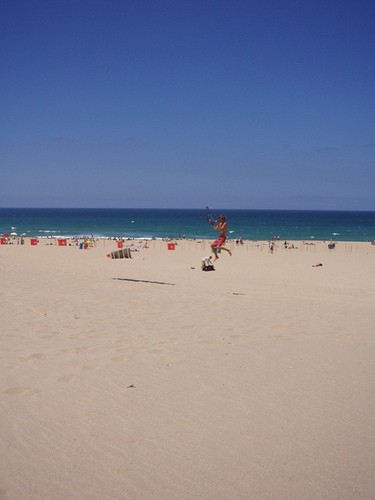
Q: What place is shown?
A: It is a beach.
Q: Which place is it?
A: It is a beach.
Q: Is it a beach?
A: Yes, it is a beach.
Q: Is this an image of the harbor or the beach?
A: It is showing the beach.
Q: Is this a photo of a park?
A: No, the picture is showing a beach.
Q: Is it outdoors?
A: Yes, it is outdoors.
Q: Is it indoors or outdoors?
A: It is outdoors.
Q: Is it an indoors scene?
A: No, it is outdoors.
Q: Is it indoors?
A: No, it is outdoors.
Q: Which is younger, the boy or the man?
A: The boy is younger than the man.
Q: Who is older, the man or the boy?
A: The man is older than the boy.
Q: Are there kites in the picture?
A: No, there are no kites.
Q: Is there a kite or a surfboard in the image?
A: No, there are no kites or surfboards.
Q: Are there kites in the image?
A: No, there are no kites.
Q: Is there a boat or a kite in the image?
A: No, there are no kites or boats.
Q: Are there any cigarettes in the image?
A: No, there are no cigarettes.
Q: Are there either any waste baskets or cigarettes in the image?
A: No, there are no cigarettes or waste baskets.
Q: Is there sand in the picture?
A: Yes, there is sand.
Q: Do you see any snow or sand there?
A: Yes, there is sand.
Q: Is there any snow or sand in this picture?
A: Yes, there is sand.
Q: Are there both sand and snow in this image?
A: No, there is sand but no snow.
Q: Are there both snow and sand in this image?
A: No, there is sand but no snow.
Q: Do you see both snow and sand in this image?
A: No, there is sand but no snow.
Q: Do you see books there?
A: No, there are no books.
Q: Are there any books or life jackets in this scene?
A: No, there are no books or life jackets.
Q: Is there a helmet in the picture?
A: No, there are no helmets.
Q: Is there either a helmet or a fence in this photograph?
A: No, there are no helmets or fences.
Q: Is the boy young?
A: Yes, the boy is young.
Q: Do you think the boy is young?
A: Yes, the boy is young.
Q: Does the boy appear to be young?
A: Yes, the boy is young.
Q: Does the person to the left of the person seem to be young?
A: Yes, the boy is young.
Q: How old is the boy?
A: The boy is young.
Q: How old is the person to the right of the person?
A: The boy is young.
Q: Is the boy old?
A: No, the boy is young.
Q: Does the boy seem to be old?
A: No, the boy is young.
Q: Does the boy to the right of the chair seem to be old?
A: No, the boy is young.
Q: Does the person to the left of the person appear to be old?
A: No, the boy is young.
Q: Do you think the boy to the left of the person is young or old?
A: The boy is young.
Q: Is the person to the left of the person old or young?
A: The boy is young.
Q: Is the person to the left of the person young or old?
A: The boy is young.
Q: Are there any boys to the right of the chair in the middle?
A: Yes, there is a boy to the right of the chair.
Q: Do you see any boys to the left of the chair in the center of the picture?
A: No, the boy is to the right of the chair.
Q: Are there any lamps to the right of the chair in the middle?
A: No, there is a boy to the right of the chair.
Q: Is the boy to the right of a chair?
A: Yes, the boy is to the right of a chair.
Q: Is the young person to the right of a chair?
A: Yes, the boy is to the right of a chair.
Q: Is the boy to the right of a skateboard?
A: No, the boy is to the right of a chair.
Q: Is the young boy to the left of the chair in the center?
A: No, the boy is to the right of the chair.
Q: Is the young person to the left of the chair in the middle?
A: No, the boy is to the right of the chair.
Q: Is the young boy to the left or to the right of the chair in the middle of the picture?
A: The boy is to the right of the chair.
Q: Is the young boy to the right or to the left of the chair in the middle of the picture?
A: The boy is to the right of the chair.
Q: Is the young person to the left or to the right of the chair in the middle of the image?
A: The boy is to the right of the chair.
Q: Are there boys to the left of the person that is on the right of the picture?
A: Yes, there is a boy to the left of the person.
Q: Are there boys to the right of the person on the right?
A: No, the boy is to the left of the person.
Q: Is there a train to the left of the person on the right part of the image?
A: No, there is a boy to the left of the person.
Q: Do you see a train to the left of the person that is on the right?
A: No, there is a boy to the left of the person.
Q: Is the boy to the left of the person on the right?
A: Yes, the boy is to the left of the person.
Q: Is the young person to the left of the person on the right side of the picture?
A: Yes, the boy is to the left of the person.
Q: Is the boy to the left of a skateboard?
A: No, the boy is to the left of the person.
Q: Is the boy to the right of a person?
A: No, the boy is to the left of a person.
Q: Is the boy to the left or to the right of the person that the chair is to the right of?
A: The boy is to the left of the person.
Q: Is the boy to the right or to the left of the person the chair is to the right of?
A: The boy is to the left of the person.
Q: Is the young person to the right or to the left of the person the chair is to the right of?
A: The boy is to the left of the person.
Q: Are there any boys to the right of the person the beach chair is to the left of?
A: Yes, there is a boy to the right of the person.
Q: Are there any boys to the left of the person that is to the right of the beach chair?
A: No, the boy is to the right of the person.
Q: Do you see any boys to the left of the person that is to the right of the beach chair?
A: No, the boy is to the right of the person.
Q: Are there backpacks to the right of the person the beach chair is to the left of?
A: No, there is a boy to the right of the person.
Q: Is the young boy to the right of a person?
A: Yes, the boy is to the right of a person.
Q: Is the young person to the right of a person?
A: Yes, the boy is to the right of a person.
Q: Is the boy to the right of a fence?
A: No, the boy is to the right of a person.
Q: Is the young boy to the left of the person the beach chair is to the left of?
A: No, the boy is to the right of the person.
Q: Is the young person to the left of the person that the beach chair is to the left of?
A: No, the boy is to the right of the person.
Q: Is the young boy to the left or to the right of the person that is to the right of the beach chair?
A: The boy is to the right of the person.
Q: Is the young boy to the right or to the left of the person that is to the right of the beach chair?
A: The boy is to the right of the person.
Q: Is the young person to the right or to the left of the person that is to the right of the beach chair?
A: The boy is to the right of the person.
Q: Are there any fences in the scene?
A: No, there are no fences.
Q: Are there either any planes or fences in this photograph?
A: No, there are no fences or planes.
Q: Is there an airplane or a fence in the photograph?
A: No, there are no fences or airplanes.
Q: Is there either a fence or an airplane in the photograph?
A: No, there are no fences or airplanes.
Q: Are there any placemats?
A: No, there are no placemats.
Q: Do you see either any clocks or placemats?
A: No, there are no placemats or clocks.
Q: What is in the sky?
A: The clouds are in the sky.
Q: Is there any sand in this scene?
A: Yes, there is sand.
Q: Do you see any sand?
A: Yes, there is sand.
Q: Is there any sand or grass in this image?
A: Yes, there is sand.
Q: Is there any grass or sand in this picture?
A: Yes, there is sand.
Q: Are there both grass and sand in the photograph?
A: No, there is sand but no grass.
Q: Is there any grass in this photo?
A: No, there is no grass.